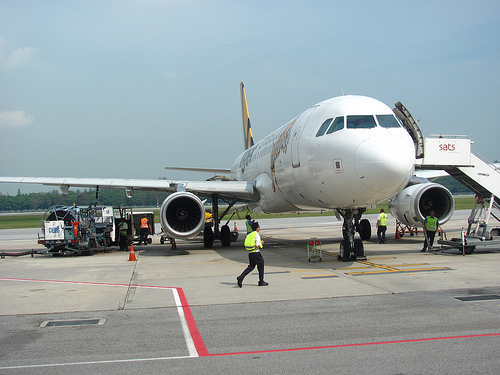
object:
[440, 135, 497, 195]
stairs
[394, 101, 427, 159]
entrance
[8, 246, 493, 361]
runeway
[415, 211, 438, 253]
employee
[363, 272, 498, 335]
tarmac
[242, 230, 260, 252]
vest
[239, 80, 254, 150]
fin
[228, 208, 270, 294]
man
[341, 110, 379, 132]
window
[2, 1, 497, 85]
sky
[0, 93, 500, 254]
airplane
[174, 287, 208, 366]
line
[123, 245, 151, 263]
orange cone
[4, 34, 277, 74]
clouds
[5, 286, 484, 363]
ground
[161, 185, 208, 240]
engine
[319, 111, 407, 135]
cockpit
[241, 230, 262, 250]
bag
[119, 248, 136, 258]
stripe